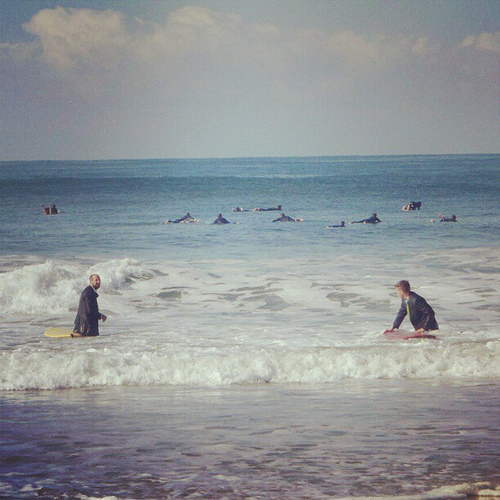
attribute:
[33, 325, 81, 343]
surfboard — yellow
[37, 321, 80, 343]
board — yellow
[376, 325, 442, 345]
board — red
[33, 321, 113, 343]
board — yellow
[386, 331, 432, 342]
board — red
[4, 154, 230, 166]
line — horizon line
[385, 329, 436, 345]
surfboard — red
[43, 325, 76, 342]
surfboard — yellow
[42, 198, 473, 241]
people — a lot/many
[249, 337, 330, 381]
water — frothy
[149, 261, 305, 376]
water — white, foamy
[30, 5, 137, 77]
cloud — fat, white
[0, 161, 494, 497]
ocean — dark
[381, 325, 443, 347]
surfboard — red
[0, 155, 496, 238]
water — blue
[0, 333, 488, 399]
water — white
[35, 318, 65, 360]
surfboard — yellow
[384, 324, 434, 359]
surfboard — red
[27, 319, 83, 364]
surfboard — yellow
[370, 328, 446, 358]
surfboard — red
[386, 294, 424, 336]
tie — yellow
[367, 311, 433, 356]
board — red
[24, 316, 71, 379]
surfboard — yellow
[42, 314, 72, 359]
surfboard — yellow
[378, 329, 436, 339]
surf board — red 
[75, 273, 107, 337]
man — standing 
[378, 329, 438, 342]
surfboard — red 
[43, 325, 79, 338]
surfboard — yellow , standing 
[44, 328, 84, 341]
surfboard — yellow 